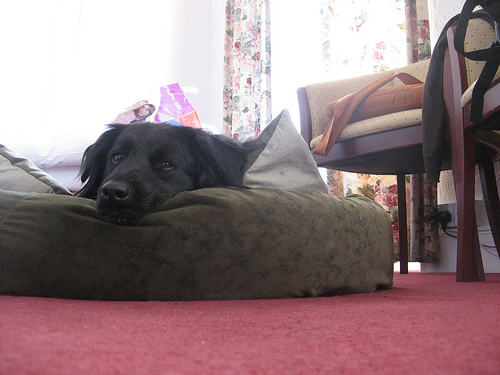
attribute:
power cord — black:
[435, 207, 497, 251]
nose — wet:
[101, 179, 130, 201]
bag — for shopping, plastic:
[113, 80, 199, 126]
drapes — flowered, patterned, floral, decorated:
[223, 1, 437, 267]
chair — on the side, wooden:
[298, 6, 500, 276]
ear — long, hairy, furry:
[77, 121, 124, 201]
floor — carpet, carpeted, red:
[1, 270, 500, 372]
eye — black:
[160, 159, 173, 169]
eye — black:
[113, 151, 124, 162]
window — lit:
[271, 3, 405, 178]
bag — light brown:
[312, 71, 424, 156]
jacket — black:
[420, 9, 496, 185]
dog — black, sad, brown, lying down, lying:
[75, 115, 258, 234]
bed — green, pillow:
[5, 146, 396, 309]